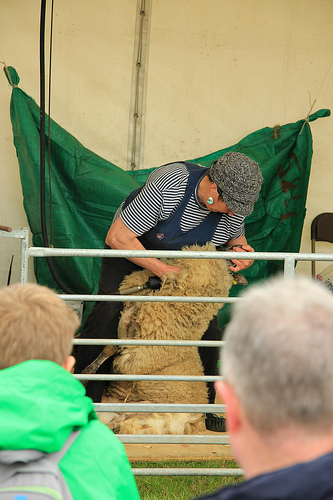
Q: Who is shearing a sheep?
A: A woman.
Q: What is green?
A: Boy's coat.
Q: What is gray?
A: Woman's hat.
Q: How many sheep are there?
A: One.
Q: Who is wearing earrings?
A: Woman.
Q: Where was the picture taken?
A: At the farm.